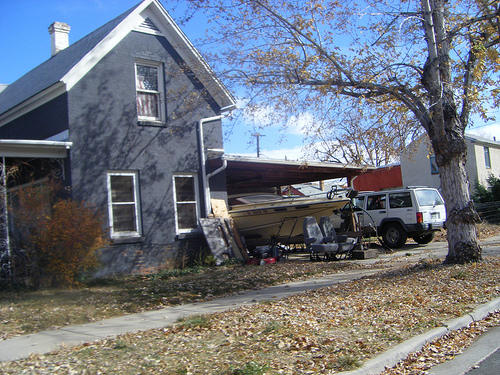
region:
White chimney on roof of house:
[41, 11, 79, 60]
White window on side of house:
[124, 49, 171, 137]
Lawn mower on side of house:
[237, 210, 305, 270]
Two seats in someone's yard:
[299, 212, 359, 270]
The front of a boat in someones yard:
[225, 177, 355, 254]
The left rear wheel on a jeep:
[376, 215, 408, 252]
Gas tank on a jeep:
[402, 209, 416, 224]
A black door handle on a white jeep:
[372, 207, 389, 217]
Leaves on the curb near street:
[435, 321, 482, 356]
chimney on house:
[49, 17, 73, 59]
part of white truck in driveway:
[350, 187, 447, 245]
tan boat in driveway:
[229, 186, 356, 231]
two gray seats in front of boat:
[304, 216, 356, 261]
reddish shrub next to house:
[14, 182, 107, 291]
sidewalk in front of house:
[0, 263, 437, 363]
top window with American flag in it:
[134, 57, 170, 124]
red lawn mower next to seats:
[246, 213, 298, 265]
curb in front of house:
[354, 303, 498, 374]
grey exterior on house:
[48, 55, 233, 272]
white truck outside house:
[332, 187, 460, 271]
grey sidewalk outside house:
[18, 247, 353, 374]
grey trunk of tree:
[368, 64, 472, 268]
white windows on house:
[90, 148, 231, 260]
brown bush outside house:
[37, 214, 118, 291]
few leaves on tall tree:
[207, 0, 425, 152]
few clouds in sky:
[244, 75, 342, 157]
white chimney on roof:
[37, 27, 68, 68]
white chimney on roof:
[45, 25, 72, 67]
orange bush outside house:
[8, 197, 125, 324]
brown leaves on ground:
[172, 270, 443, 367]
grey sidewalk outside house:
[10, 260, 400, 361]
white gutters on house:
[164, 111, 229, 201]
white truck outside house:
[340, 187, 421, 254]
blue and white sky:
[237, 43, 378, 145]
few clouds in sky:
[222, 61, 333, 145]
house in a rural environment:
[11, 7, 476, 362]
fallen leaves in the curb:
[401, 325, 451, 370]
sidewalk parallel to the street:
[82, 306, 192, 336]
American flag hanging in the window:
[130, 51, 165, 126]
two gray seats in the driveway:
[296, 212, 356, 262]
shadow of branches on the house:
[75, 105, 136, 162]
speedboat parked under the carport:
[230, 185, 350, 245]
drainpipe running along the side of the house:
[190, 110, 230, 215]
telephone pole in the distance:
[245, 125, 270, 151]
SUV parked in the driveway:
[368, 183, 441, 239]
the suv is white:
[352, 184, 445, 249]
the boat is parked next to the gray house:
[0, 1, 377, 283]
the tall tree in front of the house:
[0, 0, 497, 285]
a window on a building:
[134, 62, 161, 116]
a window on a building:
[105, 170, 141, 237]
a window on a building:
[177, 165, 199, 228]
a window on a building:
[481, 144, 493, 170]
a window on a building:
[426, 150, 440, 176]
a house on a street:
[1, 5, 375, 272]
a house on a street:
[343, 120, 498, 220]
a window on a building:
[24, 186, 51, 237]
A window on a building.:
[106, 171, 136, 202]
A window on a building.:
[172, 175, 195, 208]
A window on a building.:
[174, 200, 205, 234]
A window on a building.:
[137, 93, 163, 117]